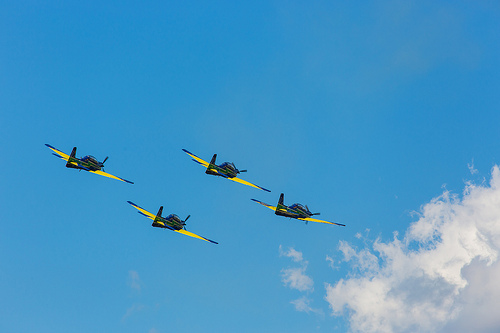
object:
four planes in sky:
[43, 141, 349, 244]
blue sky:
[0, 0, 499, 333]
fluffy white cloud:
[323, 159, 500, 332]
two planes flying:
[44, 144, 272, 193]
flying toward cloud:
[247, 193, 342, 228]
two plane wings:
[228, 177, 277, 211]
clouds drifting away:
[277, 250, 318, 313]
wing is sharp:
[250, 197, 276, 210]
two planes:
[181, 147, 346, 226]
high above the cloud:
[0, 0, 499, 62]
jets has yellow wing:
[45, 143, 132, 184]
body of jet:
[65, 155, 102, 170]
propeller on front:
[102, 156, 108, 172]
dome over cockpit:
[220, 161, 236, 171]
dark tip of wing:
[203, 238, 217, 244]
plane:
[250, 192, 347, 227]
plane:
[126, 199, 219, 245]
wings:
[174, 228, 220, 246]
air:
[0, 0, 499, 333]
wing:
[174, 138, 207, 168]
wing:
[170, 228, 217, 246]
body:
[152, 214, 182, 228]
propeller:
[231, 163, 246, 175]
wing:
[45, 143, 70, 160]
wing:
[298, 217, 346, 227]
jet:
[183, 148, 270, 193]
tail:
[205, 154, 216, 174]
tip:
[255, 185, 272, 193]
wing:
[228, 175, 271, 193]